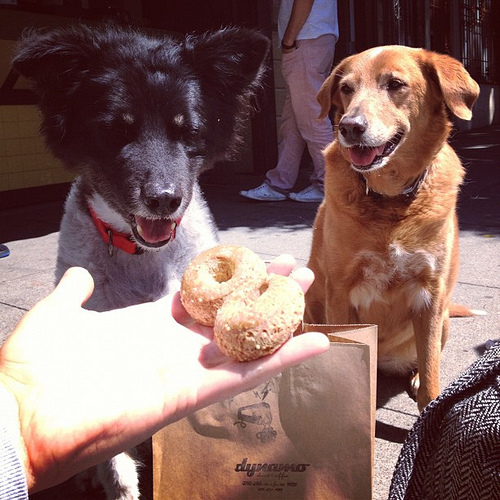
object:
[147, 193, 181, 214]
nose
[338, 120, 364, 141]
nose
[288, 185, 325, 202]
shoe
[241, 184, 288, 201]
shoe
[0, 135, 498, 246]
shadow line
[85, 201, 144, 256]
collar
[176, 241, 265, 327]
donuts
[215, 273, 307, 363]
donut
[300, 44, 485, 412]
dog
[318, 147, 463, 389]
fur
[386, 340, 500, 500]
fabric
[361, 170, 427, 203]
collar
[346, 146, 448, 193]
dog's neck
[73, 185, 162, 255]
dog's neck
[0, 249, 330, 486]
hand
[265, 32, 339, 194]
brown pants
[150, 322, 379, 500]
bag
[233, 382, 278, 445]
logo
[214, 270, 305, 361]
doughnuts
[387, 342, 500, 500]
hat?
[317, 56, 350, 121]
ear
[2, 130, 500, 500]
sidewalk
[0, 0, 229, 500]
dog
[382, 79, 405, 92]
eye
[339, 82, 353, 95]
eye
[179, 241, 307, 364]
food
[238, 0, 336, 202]
man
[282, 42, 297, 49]
wristband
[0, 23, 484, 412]
two dogs